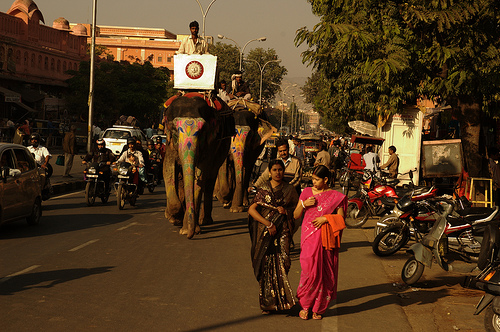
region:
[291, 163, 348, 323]
young indian woman dress in pink clothing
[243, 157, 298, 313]
young indian woman dressed in dark colored clothing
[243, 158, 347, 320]
two young woman walking on a street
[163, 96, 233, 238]
a gray elephant with a colorfully painted snout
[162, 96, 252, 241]
two elephants walking down a street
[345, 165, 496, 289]
a bunch of parked motorcycles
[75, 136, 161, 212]
group of people riding motorcycles on a street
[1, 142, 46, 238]
vehicle on a street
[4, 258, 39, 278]
white dash line on a street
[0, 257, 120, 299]
a shadow on the ground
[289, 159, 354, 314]
woman in pink dress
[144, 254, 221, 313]
grey pavement on road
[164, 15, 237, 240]
man riding on large elephant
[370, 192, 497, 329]
row of parked motor scooters beside road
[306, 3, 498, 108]
large tree with green leaves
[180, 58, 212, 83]
design on front of elephant basket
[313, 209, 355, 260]
orange fabric draped over arm of woman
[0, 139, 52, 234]
car driving on road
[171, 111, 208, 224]
multi-coloured painted elephant trunk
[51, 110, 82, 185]
person standing on side of road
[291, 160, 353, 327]
This is a person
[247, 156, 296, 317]
This is a person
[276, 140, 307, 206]
This is a person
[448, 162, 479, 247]
This is a person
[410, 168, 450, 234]
This is a person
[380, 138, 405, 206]
This is a person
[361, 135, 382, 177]
This is a person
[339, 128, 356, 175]
This is a person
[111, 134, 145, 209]
This is a person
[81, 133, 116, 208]
This is a person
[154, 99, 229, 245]
elephant with decorated trunk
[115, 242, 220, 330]
grey pavement on road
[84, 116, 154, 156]
white vehicle parked on side of road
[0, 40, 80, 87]
row of windows on side of building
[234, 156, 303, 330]
woman in brown dress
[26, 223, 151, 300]
white lines painted on road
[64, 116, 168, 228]
people on moto bikes driving on road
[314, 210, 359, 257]
orange clothing on arm of woman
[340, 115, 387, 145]
grey and white umbrella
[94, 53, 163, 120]
tree covered in green leaves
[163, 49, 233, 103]
There is a design on the container.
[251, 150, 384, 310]
The women are walking.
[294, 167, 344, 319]
This woman's dress is pink.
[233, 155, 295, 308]
This woman's dress is brown.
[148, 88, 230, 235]
This is an elephant.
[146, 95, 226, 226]
The elephant is painted.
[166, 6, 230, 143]
The man is riding the elephant.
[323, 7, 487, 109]
The tree's leaves are very green.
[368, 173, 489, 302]
These are scooters.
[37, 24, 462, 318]
This could be in India.